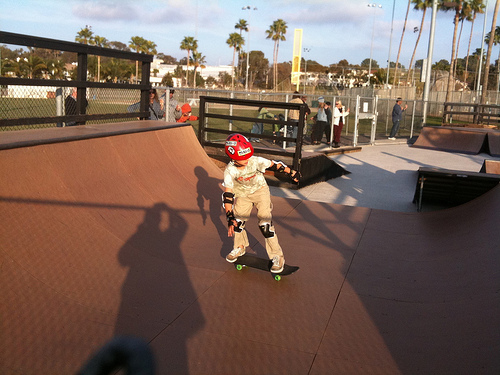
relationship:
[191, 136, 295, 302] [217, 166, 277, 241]
skater wears safety gear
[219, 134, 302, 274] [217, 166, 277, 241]
skater wears safety gear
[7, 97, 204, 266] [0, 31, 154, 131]
ramp has fence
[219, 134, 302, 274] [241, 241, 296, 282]
skater on skateboard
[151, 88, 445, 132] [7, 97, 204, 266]
fence behind ramp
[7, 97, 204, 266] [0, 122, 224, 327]
ramp has ramp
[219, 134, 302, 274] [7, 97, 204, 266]
skater near ramp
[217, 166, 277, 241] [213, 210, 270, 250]
safety gear on knees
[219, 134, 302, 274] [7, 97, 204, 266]
skater inside ramp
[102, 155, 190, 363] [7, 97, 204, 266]
shadow on ramp